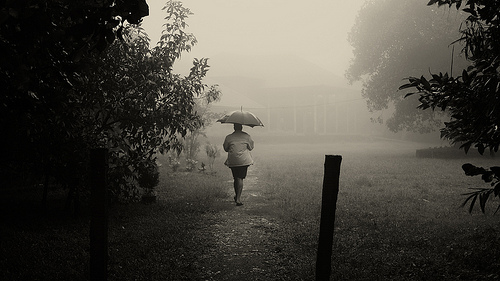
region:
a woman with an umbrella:
[212, 103, 265, 208]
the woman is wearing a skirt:
[220, 121, 255, 206]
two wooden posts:
[76, 140, 351, 275]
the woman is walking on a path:
[205, 106, 280, 276]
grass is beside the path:
[252, 140, 497, 275]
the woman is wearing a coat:
[220, 130, 257, 170]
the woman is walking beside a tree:
[45, 1, 257, 211]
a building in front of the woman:
[215, 80, 395, 150]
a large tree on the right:
[340, 1, 495, 161]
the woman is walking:
[214, 101, 267, 206]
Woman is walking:
[209, 77, 265, 202]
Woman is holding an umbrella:
[218, 93, 267, 138]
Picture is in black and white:
[13, 5, 487, 263]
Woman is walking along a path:
[204, 180, 270, 278]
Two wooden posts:
[72, 137, 379, 269]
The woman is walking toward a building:
[214, 51, 344, 207]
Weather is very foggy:
[213, 24, 339, 104]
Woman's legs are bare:
[226, 170, 252, 203]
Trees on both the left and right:
[20, 5, 489, 158]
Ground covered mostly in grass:
[358, 130, 422, 260]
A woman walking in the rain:
[209, 85, 284, 223]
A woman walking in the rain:
[211, 99, 260, 204]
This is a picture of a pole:
[267, 152, 378, 277]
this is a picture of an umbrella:
[179, 73, 261, 147]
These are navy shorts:
[88, 163, 282, 205]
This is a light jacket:
[215, 132, 249, 162]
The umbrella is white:
[215, 111, 250, 126]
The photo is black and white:
[165, 100, 375, 261]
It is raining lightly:
[305, 205, 415, 275]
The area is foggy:
[295, 36, 425, 246]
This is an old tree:
[102, 93, 147, 146]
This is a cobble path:
[230, 223, 280, 266]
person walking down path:
[209, 101, 261, 206]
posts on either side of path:
[84, 142, 346, 276]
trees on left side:
[6, 10, 220, 280]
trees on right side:
[348, 13, 499, 234]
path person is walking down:
[195, 146, 289, 271]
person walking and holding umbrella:
[213, 103, 267, 208]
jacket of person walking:
[223, 137, 253, 165]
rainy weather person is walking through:
[128, 9, 495, 266]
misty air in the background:
[140, 12, 412, 143]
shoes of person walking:
[230, 195, 245, 205]